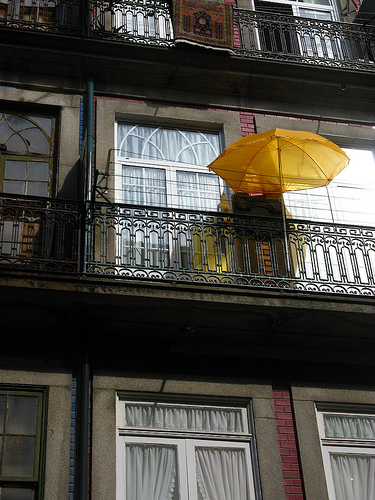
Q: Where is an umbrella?
A: On a balcony.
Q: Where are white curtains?
A: Inside the windows.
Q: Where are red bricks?
A: On the building.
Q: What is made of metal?
A: The railings.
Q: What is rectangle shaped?
A: The windows.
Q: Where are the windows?
A: On side of a building.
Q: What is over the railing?
A: Umbrella.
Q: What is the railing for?
A: Guard.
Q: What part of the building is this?
A: Patio.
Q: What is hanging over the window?
A: Curtains.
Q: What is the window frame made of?
A: Concrete.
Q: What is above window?
A: Smaller window.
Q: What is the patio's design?
A: Decorative.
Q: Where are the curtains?
A: Inside window.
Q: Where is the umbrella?
A: On the balcony.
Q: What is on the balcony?
A: An umbrella.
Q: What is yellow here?
A: An umbrella.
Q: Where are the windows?
A: On the building.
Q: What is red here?
A: Bricks.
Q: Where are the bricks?
A: On the building.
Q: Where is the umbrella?
A: On the terrace.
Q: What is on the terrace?
A: An umbrella.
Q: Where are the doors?
A: On the terraces.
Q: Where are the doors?
A: On the building.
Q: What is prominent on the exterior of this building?
A: Windows.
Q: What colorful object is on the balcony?
A: Umbrella.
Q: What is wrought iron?
A: Fence.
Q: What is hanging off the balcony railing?
A: Carpet.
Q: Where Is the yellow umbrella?
A: 2nd Floor.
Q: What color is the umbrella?
A: Yellow.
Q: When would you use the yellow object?
A: If it is raining.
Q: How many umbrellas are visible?
A: One.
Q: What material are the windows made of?
A: Glass.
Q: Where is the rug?
A: On the top railing.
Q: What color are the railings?
A: Black.